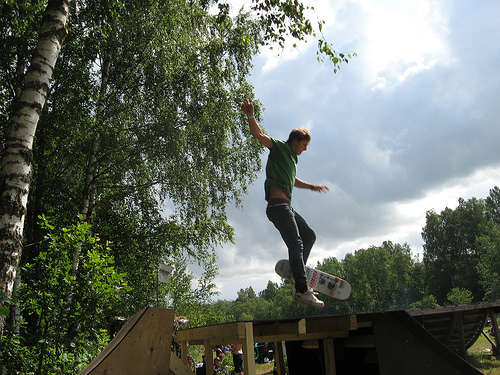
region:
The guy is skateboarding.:
[231, 101, 348, 306]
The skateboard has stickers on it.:
[274, 253, 359, 303]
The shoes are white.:
[276, 285, 336, 310]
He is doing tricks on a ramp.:
[76, 287, 499, 372]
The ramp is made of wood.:
[128, 325, 365, 372]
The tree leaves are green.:
[51, 234, 125, 326]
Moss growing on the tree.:
[0, 18, 60, 319]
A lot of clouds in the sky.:
[268, 61, 495, 189]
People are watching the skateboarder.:
[155, 338, 245, 373]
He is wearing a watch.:
[233, 97, 271, 128]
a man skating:
[234, 85, 349, 303]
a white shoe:
[288, 281, 323, 313]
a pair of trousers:
[269, 191, 326, 297]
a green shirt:
[260, 131, 304, 210]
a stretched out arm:
[236, 90, 278, 144]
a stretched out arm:
[291, 175, 331, 207]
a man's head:
[282, 117, 311, 161]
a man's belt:
[258, 198, 290, 210]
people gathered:
[176, 315, 288, 372]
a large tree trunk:
[1, 9, 73, 318]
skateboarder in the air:
[236, 95, 366, 320]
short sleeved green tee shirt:
[259, 130, 300, 205]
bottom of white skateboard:
[271, 256, 356, 308]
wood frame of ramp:
[248, 311, 368, 372]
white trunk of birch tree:
[7, 63, 59, 191]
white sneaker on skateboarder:
[287, 281, 329, 314]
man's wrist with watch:
[233, 93, 261, 133]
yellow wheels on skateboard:
[324, 273, 346, 303]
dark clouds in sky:
[375, 128, 462, 207]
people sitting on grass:
[194, 341, 246, 373]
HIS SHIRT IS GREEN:
[261, 131, 312, 206]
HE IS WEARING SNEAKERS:
[273, 251, 358, 312]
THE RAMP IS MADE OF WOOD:
[71, 298, 226, 372]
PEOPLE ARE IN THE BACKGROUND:
[192, 333, 249, 373]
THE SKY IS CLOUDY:
[368, 41, 492, 189]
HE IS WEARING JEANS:
[261, 196, 321, 268]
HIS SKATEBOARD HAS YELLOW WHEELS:
[318, 265, 358, 309]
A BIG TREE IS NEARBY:
[6, 20, 63, 343]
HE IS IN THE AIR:
[227, 89, 369, 314]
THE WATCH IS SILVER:
[238, 95, 260, 131]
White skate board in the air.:
[228, 263, 372, 322]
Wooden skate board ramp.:
[44, 255, 186, 372]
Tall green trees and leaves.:
[355, 177, 493, 330]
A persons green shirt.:
[235, 142, 315, 236]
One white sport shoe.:
[265, 287, 328, 314]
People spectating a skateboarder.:
[181, 336, 241, 371]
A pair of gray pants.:
[258, 185, 353, 347]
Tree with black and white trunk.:
[0, 107, 162, 348]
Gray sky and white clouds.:
[332, 116, 469, 204]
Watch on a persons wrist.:
[216, 86, 284, 128]